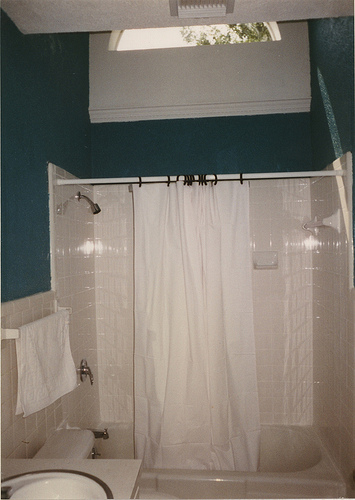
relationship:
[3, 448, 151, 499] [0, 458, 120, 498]
counter with sink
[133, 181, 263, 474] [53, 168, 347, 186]
shower curtain on rod